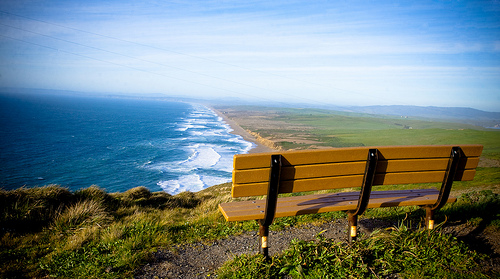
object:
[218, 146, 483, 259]
bench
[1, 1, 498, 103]
sky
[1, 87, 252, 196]
sea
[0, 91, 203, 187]
ocean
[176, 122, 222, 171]
waves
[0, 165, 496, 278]
cliff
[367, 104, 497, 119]
mountain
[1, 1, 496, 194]
distance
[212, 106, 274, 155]
beach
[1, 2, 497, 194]
view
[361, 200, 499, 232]
shadow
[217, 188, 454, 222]
seat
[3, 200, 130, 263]
grass